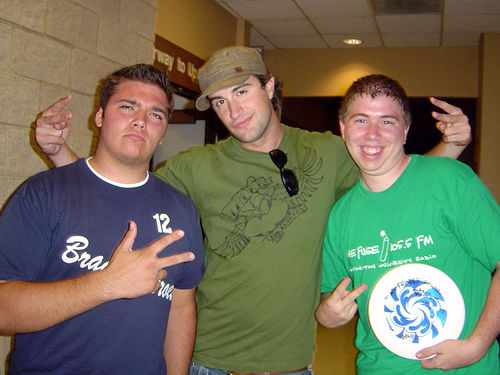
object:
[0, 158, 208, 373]
t-shirt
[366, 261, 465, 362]
frisbee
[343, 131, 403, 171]
smiling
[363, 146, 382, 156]
teeth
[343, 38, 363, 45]
light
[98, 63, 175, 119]
hair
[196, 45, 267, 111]
green hat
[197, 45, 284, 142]
head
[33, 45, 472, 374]
boy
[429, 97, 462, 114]
finger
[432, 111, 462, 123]
finger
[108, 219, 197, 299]
hand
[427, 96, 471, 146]
hand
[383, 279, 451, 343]
signs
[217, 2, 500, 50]
ceiling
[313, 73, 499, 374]
boy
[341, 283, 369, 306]
finger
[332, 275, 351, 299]
finger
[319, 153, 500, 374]
shirt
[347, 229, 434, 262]
radio station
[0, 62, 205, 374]
boy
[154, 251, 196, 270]
fingers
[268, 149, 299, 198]
sunglasses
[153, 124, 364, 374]
man's shirt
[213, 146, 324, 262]
design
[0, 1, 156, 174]
wall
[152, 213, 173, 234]
12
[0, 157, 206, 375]
blue shirt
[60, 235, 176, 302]
writing